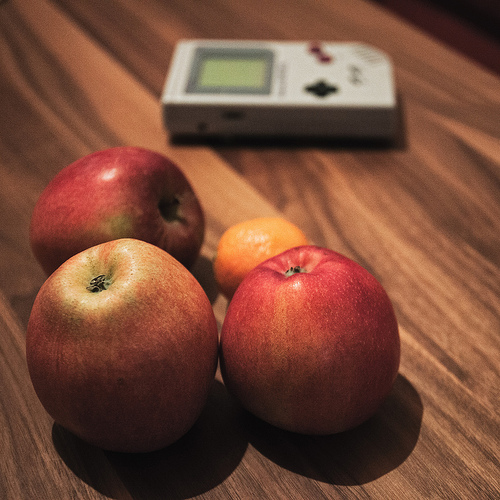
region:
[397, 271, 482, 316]
Brown wood grain table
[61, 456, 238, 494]
Shadow of the apple in the left front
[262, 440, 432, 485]
Shadow of the apple in the right front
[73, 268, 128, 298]
Bottom end (opposite the stem end) of the left front apple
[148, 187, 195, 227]
Stem of the apple in the back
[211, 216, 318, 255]
Orange by itself among three apples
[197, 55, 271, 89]
Green square inside the black rim of the device on the table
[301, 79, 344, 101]
Black cross on the device on the table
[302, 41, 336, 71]
Two red diagonal dots on the device on the table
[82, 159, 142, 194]
Shiny spot on the apple in the rear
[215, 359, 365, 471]
a shadow is cast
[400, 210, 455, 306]
the table is made of wood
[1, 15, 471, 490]
the room is well lit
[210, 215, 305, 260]
the orange fruit is orange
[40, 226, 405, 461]
the apples are yellow and red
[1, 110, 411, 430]
the apples are three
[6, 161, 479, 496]
it is an indoor scene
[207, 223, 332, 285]
the orange is one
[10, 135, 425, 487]
Fruits on a table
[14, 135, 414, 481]
Three apples on a table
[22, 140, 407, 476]
Apples are red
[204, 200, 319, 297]
Tangerine in middle of apples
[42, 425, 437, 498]
Shadows of apples cast on the table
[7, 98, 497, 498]
Table is brown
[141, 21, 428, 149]
Game boy close to fruits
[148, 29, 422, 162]
Game boy is tan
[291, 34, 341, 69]
Game boy has a red button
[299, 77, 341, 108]
Game boy has a black button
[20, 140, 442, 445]
apples and a tangerine on table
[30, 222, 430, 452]
bottom of apples facing up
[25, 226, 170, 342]
swelling around blossom-end of fruit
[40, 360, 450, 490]
shadow of apples across the table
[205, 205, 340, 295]
apple hiding part of tangerine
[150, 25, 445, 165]
gaming device with window on top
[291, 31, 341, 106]
black and red buttons on surface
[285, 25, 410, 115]
slanted corner on lower right side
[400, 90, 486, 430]
brown and tan surface of table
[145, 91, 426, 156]
functional portals on side of device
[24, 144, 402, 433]
three apples and one orange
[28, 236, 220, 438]
red and green apple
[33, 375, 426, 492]
apples are casting shadows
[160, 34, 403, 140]
old style gameboy in background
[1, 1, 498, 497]
wood table looks like veneer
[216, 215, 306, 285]
tangerine looks like cutie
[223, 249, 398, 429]
apple is all red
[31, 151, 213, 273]
apple is tilted to the side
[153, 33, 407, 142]
gameboy is out of focus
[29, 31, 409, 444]
apples are in front of gameboy